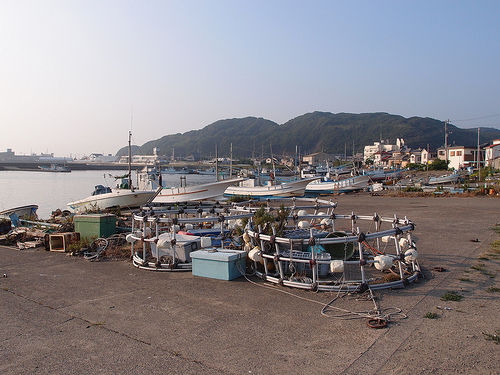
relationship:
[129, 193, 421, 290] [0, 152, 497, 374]
rings on ground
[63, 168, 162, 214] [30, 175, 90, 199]
boat out of water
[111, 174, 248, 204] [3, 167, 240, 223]
boat out of water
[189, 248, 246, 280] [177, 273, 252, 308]
box on ground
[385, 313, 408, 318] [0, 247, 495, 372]
rope on ground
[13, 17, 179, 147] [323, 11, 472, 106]
white clouds in blue sky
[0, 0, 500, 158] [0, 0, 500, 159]
white clouds in blue sky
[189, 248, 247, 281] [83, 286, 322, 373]
box on ground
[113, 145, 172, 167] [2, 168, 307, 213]
boat out of water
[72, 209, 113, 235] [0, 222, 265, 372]
green box on ground